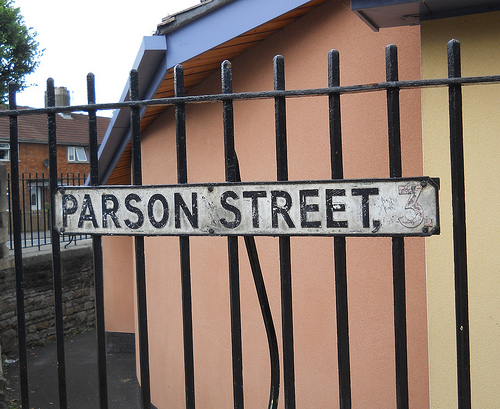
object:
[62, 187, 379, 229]
parson street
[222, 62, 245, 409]
bar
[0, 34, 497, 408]
fence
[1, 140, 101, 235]
wall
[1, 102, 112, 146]
roof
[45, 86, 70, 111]
chimney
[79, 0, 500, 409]
building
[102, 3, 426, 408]
wall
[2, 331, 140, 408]
ground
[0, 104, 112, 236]
building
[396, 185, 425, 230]
number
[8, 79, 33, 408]
rod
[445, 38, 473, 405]
rod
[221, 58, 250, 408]
rod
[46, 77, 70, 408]
rod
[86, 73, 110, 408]
rod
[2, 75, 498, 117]
pole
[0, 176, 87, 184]
pole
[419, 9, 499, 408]
wall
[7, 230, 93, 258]
ground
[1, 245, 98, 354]
wall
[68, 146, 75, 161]
window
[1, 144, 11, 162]
window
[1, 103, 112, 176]
top